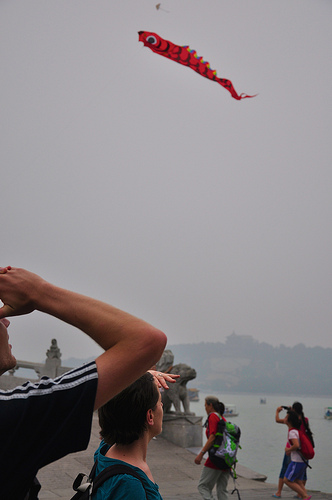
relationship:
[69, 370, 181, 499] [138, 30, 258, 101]
person looking at kite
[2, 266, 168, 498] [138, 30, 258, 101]
person looking at kite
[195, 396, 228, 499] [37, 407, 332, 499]
person walking along street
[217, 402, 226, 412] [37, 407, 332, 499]
person walking along street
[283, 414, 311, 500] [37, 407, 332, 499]
person walking along street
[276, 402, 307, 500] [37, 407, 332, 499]
person walking along street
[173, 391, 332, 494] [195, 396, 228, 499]
ocean behind person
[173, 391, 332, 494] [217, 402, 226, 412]
ocean behind person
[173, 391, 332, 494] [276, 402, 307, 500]
ocean behind person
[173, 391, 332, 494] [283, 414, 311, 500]
ocean behind person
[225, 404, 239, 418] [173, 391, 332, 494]
boat in water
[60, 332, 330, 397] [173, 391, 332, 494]
hill behind ocean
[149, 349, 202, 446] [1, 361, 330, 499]
statue on plaza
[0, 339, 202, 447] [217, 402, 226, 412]
wall next to person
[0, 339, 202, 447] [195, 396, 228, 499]
wall next to person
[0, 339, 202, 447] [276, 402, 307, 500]
wall next to person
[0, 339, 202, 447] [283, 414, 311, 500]
wall next to person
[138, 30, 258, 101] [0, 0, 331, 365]
kite in sky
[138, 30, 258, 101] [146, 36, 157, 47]
kite has eye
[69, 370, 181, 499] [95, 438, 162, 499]
woman has shirt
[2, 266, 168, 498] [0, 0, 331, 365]
person looks at sky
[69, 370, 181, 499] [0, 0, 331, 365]
person looks at sky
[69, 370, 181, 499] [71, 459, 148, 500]
person wears backpack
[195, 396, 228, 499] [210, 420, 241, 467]
person wears backpack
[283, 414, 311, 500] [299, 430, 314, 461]
person wears backpack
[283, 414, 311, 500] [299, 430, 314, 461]
child has backpack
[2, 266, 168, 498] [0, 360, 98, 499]
man has shirt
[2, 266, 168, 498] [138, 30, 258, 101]
man looking up at kite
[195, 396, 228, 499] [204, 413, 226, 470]
person wearing shirt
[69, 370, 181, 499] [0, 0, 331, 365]
woman looking up in sky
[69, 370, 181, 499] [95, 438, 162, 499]
woman wearing shirt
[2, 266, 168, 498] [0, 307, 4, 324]
person shielding eyes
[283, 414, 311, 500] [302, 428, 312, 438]
woman with baby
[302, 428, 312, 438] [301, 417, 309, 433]
baby on back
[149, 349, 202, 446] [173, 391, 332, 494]
statue by water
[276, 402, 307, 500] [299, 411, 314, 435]
woman with pony tail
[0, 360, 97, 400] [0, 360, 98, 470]
stripes on sleeve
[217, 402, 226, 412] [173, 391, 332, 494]
person near body of water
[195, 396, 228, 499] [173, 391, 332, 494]
person near body of water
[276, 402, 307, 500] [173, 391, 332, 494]
person near body of water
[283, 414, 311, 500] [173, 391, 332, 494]
person near body of water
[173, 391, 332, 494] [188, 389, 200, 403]
water with boat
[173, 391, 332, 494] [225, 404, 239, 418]
water with boat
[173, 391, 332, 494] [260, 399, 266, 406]
water with boat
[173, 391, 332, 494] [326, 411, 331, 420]
water with boat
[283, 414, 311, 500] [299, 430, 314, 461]
youngster with backpack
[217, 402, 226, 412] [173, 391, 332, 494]
person walking by water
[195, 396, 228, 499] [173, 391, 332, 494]
person walking by water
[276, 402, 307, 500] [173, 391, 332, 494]
person walking by water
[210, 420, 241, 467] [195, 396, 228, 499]
backpack belongs to man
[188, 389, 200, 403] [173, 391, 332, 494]
boat in water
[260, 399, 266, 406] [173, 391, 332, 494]
boat in water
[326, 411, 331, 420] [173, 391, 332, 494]
boat in water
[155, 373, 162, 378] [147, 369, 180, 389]
ring on hand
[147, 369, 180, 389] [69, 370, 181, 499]
hand belongs to woman